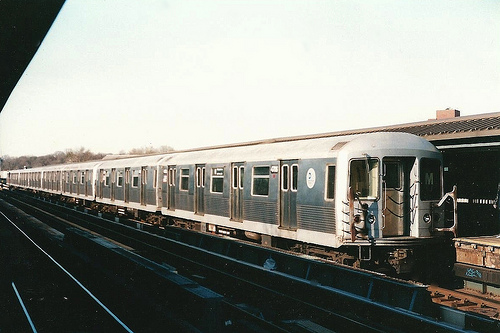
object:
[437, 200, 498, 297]
boarding platform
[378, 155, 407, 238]
door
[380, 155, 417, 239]
doorway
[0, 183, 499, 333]
rails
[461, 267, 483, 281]
graffiti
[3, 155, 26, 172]
trees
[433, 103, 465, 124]
chimney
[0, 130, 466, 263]
train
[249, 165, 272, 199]
window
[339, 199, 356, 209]
chains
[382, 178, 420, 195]
chains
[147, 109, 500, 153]
roof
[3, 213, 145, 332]
rail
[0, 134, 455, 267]
side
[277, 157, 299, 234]
door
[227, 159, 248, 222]
door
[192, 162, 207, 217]
door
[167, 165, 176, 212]
door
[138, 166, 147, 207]
door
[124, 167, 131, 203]
door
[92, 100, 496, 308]
building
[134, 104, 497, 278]
train station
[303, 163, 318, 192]
sign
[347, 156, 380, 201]
window